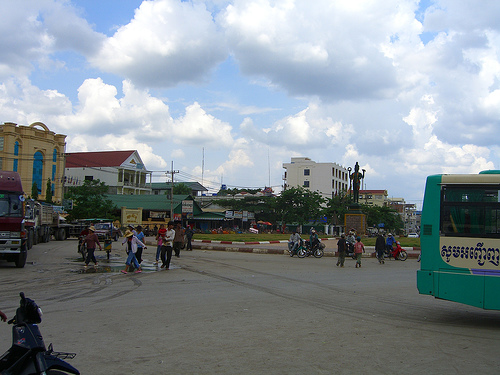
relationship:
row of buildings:
[63, 141, 359, 226] [0, 116, 415, 244]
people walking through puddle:
[77, 219, 178, 271] [68, 251, 174, 277]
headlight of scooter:
[25, 293, 49, 325] [2, 292, 83, 372]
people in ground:
[60, 214, 411, 275] [8, 230, 456, 374]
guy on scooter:
[306, 228, 329, 262] [311, 238, 329, 262]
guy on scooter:
[288, 227, 302, 256] [285, 237, 314, 259]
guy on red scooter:
[385, 229, 398, 258] [388, 236, 412, 263]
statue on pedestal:
[347, 158, 370, 202] [337, 157, 375, 240]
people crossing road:
[60, 214, 411, 275] [8, 230, 456, 374]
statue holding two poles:
[347, 158, 370, 202] [346, 169, 368, 200]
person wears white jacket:
[117, 229, 149, 278] [118, 234, 148, 256]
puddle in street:
[68, 251, 174, 277] [8, 230, 456, 374]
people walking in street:
[60, 214, 411, 275] [8, 230, 456, 374]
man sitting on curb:
[288, 227, 302, 256] [194, 244, 289, 253]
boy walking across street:
[352, 232, 370, 268] [8, 230, 456, 374]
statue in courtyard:
[347, 158, 370, 202] [200, 222, 410, 246]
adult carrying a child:
[155, 219, 179, 273] [154, 221, 171, 244]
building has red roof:
[67, 147, 150, 191] [66, 147, 149, 168]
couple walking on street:
[333, 230, 369, 270] [8, 230, 456, 374]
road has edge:
[8, 230, 456, 374] [193, 241, 285, 259]